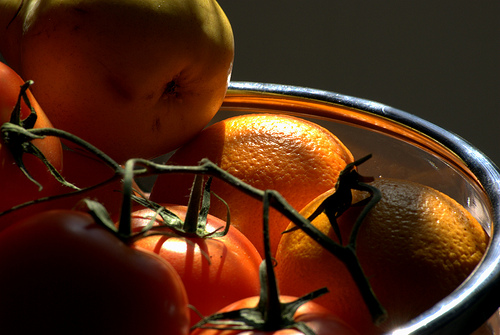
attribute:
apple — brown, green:
[21, 0, 235, 159]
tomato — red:
[111, 204, 264, 328]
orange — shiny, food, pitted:
[149, 114, 358, 260]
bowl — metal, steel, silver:
[125, 81, 498, 335]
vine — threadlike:
[25, 129, 387, 329]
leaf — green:
[132, 176, 233, 237]